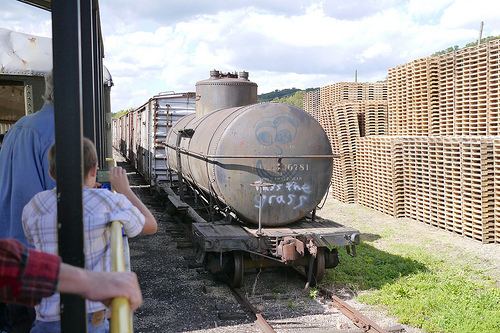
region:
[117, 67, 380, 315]
A train driving away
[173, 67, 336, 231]
A metal tank with a smiley drawn on it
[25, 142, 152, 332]
A kid taking a picture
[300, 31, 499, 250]
Stacks of wooden pallets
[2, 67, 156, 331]
A small group of people watching a train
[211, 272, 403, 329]
A portion of train tracks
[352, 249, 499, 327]
A small patch of green grass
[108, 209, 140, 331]
A yellow hand rail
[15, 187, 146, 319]
A white and blue plaid shirt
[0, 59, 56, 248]
A man in a blue shirt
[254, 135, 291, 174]
part of a metal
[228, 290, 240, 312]
edge of a rail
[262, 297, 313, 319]
part of a rail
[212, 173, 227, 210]
edge of a train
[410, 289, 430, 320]
part of a ground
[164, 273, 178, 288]
part of a ground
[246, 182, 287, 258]
part of a metal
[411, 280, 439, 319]
part of a ground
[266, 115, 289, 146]
part of a train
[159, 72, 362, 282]
a tanke train car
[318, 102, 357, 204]
a tipping stack of pallets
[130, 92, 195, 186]
a gray boxcar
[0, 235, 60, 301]
a red plaid shirt sleef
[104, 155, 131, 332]
a yellow hand rail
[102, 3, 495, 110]
a blue and white cloudy sky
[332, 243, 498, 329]
a strip of grass next to the tracks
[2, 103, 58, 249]
a blue shirt on a man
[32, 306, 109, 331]
jeans on a boy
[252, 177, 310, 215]
white graffiti on a tanker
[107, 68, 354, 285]
old and rusty train on the tracks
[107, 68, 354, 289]
long train on the tracks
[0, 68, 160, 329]
group of people looking at the train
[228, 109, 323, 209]
graffiti on the front of the train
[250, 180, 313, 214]
pass the grass spray painted on the train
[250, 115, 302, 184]
blue face painted on the train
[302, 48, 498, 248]
piles of wooden pallets next to the train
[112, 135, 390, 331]
rail road tracks with a train on it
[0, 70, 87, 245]
man in a blue shirt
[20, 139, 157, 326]
little boy in a white shirt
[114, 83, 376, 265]
Aging freight train cars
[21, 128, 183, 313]
Man taking picture with cell phone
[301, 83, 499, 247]
Stacked pallets on railroad side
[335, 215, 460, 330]
Green grass growing by rails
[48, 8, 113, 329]
Metal pole block man with phone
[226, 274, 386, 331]
Rusted railroad tracks on ground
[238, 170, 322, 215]
White spray paint on train car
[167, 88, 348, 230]
Black train car for carrying chemicals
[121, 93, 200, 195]
Rusty white boxcar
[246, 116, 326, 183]
Smiley face drawn on train car